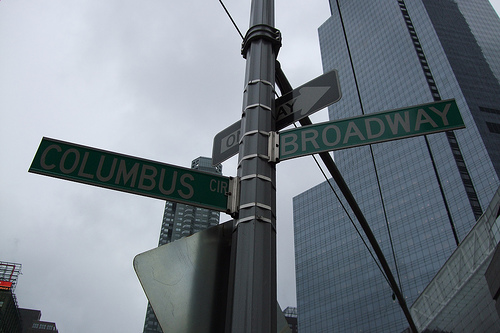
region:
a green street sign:
[277, 95, 467, 162]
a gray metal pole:
[231, 0, 284, 330]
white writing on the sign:
[280, 98, 455, 156]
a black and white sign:
[206, 64, 348, 166]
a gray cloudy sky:
[0, 0, 334, 332]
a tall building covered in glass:
[288, 0, 499, 331]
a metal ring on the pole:
[231, 210, 279, 233]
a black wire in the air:
[217, 0, 427, 332]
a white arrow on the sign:
[218, 81, 330, 151]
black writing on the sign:
[222, 123, 245, 146]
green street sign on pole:
[276, 115, 471, 155]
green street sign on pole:
[48, 143, 224, 213]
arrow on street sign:
[269, 80, 331, 121]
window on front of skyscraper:
[397, 242, 406, 258]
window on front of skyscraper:
[411, 220, 424, 235]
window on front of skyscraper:
[297, 254, 307, 271]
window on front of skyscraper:
[291, 208, 299, 222]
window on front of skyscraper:
[296, 277, 303, 292]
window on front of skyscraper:
[297, 257, 302, 269]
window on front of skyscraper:
[294, 232, 299, 244]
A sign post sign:
[19, 130, 239, 229]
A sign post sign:
[274, 87, 474, 169]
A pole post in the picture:
[229, 0, 282, 332]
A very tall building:
[137, 146, 225, 331]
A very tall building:
[283, 1, 498, 331]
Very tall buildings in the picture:
[0, 255, 70, 332]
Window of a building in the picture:
[307, 202, 314, 217]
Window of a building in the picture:
[312, 230, 324, 250]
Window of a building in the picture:
[322, 262, 342, 287]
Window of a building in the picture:
[355, 288, 371, 311]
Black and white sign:
[177, 48, 348, 173]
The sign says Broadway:
[263, 74, 461, 183]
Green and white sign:
[253, 94, 463, 191]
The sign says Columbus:
[31, 120, 242, 220]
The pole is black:
[212, 7, 285, 322]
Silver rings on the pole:
[225, 58, 285, 238]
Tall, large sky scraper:
[283, 1, 490, 326]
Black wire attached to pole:
[246, 26, 438, 321]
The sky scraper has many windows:
[299, 8, 485, 330]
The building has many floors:
[126, 141, 231, 331]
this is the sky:
[84, 40, 176, 116]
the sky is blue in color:
[154, 52, 194, 98]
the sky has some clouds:
[31, 39, 138, 125]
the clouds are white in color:
[34, 48, 81, 93]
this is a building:
[329, 27, 490, 332]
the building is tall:
[329, 22, 415, 327]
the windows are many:
[353, 28, 404, 93]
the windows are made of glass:
[367, 44, 399, 70]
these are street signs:
[29, 58, 479, 220]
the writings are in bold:
[291, 130, 407, 150]